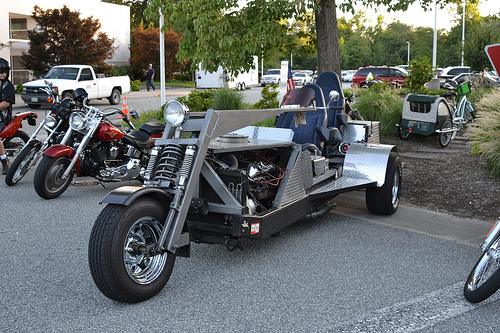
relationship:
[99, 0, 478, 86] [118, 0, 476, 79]
tree in leaves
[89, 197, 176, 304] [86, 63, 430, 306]
tire in bike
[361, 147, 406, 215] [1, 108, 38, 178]
tire on bike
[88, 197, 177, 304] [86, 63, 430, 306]
tire on bike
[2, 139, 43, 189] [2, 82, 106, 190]
tire on bike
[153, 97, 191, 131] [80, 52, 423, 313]
light on bike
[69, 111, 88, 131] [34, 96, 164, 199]
light on bike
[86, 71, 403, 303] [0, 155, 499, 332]
bike on street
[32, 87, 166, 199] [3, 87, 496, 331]
bike on street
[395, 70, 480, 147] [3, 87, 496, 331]
bicycle on street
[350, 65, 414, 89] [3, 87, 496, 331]
car on street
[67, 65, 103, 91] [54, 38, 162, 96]
sticker on car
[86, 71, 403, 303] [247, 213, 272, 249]
bike has sticker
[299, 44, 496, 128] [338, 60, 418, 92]
car has sticker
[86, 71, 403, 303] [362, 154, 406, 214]
bike has tire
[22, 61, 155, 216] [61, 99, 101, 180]
bike has fork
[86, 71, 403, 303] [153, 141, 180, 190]
bike has spring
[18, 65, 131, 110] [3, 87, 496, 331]
car in street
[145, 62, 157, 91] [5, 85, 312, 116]
man walking down street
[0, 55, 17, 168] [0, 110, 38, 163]
person sitting bike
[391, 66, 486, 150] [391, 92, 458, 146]
bicycle pulling holder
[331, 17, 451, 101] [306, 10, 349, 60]
tree has trunk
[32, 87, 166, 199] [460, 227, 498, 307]
bike has tire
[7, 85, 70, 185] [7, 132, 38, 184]
bike has tire bike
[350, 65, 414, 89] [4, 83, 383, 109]
car on street